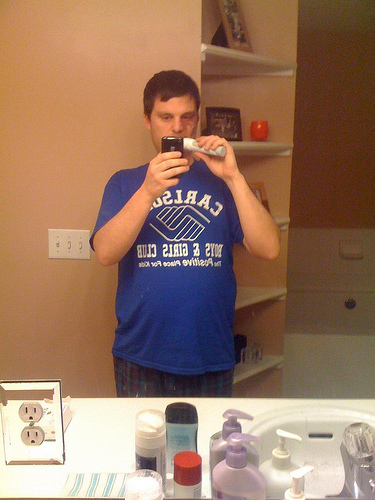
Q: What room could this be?
A: It is a bathroom.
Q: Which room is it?
A: It is a bathroom.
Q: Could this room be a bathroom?
A: Yes, it is a bathroom.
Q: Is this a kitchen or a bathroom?
A: It is a bathroom.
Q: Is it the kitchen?
A: No, it is the bathroom.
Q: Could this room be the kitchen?
A: No, it is the bathroom.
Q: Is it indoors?
A: Yes, it is indoors.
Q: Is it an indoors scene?
A: Yes, it is indoors.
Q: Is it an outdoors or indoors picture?
A: It is indoors.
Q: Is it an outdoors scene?
A: No, it is indoors.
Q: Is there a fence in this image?
A: No, there are no fences.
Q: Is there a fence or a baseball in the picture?
A: No, there are no fences or baseballs.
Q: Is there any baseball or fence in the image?
A: No, there are no fences or baseballs.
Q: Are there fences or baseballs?
A: No, there are no fences or baseballs.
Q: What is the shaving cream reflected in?
A: The shaving cream is reflected in the mirror.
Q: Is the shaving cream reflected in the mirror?
A: Yes, the shaving cream is reflected in the mirror.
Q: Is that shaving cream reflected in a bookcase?
A: No, the shaving cream is reflected in the mirror.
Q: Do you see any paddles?
A: No, there are no paddles.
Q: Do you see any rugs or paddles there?
A: No, there are no paddles or rugs.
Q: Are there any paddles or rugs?
A: No, there are no paddles or rugs.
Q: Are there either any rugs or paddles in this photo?
A: No, there are no paddles or rugs.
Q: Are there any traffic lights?
A: No, there are no traffic lights.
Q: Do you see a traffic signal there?
A: No, there are no traffic lights.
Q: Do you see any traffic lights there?
A: No, there are no traffic lights.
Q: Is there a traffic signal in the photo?
A: No, there are no traffic lights.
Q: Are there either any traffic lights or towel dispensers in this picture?
A: No, there are no traffic lights or towel dispensers.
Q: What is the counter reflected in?
A: The counter is reflected in the mirror.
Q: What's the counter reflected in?
A: The counter is reflected in the mirror.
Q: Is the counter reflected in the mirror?
A: Yes, the counter is reflected in the mirror.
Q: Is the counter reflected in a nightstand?
A: No, the counter is reflected in the mirror.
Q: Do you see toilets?
A: No, there are no toilets.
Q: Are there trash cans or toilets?
A: No, there are no toilets or trash cans.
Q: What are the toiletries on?
A: The toiletries are on the counter.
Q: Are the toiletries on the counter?
A: Yes, the toiletries are on the counter.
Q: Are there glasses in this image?
A: No, there are no glasses.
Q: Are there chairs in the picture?
A: No, there are no chairs.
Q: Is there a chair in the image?
A: No, there are no chairs.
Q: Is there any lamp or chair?
A: No, there are no chairs or lamps.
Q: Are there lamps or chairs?
A: No, there are no chairs or lamps.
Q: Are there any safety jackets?
A: No, there are no safety jackets.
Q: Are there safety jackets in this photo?
A: No, there are no safety jackets.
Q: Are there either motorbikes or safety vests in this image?
A: No, there are no safety vests or motorbikes.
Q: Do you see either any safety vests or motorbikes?
A: No, there are no safety vests or motorbikes.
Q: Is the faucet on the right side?
A: Yes, the faucet is on the right of the image.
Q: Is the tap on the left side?
A: No, the tap is on the right of the image.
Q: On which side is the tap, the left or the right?
A: The tap is on the right of the image.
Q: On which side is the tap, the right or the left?
A: The tap is on the right of the image.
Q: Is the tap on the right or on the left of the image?
A: The tap is on the right of the image.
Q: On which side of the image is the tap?
A: The tap is on the right of the image.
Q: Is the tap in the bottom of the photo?
A: Yes, the tap is in the bottom of the image.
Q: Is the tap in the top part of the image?
A: No, the tap is in the bottom of the image.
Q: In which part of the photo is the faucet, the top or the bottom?
A: The faucet is in the bottom of the image.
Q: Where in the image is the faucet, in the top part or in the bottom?
A: The faucet is in the bottom of the image.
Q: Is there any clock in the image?
A: No, there are no clocks.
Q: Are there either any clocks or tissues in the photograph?
A: No, there are no clocks or tissues.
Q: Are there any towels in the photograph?
A: Yes, there is a towel.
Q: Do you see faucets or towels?
A: Yes, there is a towel.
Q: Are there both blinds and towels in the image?
A: No, there is a towel but no blinds.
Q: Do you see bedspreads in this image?
A: No, there are no bedspreads.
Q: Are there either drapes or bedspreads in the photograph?
A: No, there are no bedspreads or drapes.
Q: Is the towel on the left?
A: Yes, the towel is on the left of the image.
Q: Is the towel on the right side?
A: No, the towel is on the left of the image.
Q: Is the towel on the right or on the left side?
A: The towel is on the left of the image.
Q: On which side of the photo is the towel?
A: The towel is on the left of the image.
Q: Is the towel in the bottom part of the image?
A: Yes, the towel is in the bottom of the image.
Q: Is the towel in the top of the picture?
A: No, the towel is in the bottom of the image.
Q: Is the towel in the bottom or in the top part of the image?
A: The towel is in the bottom of the image.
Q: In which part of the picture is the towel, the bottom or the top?
A: The towel is in the bottom of the image.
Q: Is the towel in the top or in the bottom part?
A: The towel is in the bottom of the image.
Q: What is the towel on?
A: The towel is on the counter.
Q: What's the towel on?
A: The towel is on the counter.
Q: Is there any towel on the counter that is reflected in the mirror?
A: Yes, there is a towel on the counter.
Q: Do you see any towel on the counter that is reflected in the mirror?
A: Yes, there is a towel on the counter.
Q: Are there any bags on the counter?
A: No, there is a towel on the counter.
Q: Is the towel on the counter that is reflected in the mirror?
A: Yes, the towel is on the counter.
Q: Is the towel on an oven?
A: No, the towel is on the counter.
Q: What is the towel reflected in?
A: The towel is reflected in the mirror.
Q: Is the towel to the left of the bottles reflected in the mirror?
A: Yes, the towel is reflected in the mirror.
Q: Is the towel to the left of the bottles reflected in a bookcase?
A: No, the towel is reflected in the mirror.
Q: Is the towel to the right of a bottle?
A: No, the towel is to the left of a bottle.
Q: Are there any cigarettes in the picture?
A: No, there are no cigarettes.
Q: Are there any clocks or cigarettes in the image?
A: No, there are no cigarettes or clocks.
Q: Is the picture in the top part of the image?
A: Yes, the picture is in the top of the image.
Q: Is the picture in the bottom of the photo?
A: No, the picture is in the top of the image.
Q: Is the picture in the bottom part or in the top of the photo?
A: The picture is in the top of the image.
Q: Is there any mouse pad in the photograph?
A: No, there are no mouse pads.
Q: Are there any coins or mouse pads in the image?
A: No, there are no mouse pads or coins.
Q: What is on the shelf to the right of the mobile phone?
A: The picture frame is on the shelf.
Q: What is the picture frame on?
A: The picture frame is on the shelf.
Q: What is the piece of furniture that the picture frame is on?
A: The piece of furniture is a shelf.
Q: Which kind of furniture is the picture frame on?
A: The picture frame is on the shelf.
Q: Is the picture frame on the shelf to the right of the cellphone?
A: Yes, the picture frame is on the shelf.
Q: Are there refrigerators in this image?
A: No, there are no refrigerators.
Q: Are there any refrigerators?
A: No, there are no refrigerators.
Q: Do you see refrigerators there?
A: No, there are no refrigerators.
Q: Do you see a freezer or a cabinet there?
A: No, there are no refrigerators or cabinets.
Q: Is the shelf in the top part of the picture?
A: Yes, the shelf is in the top of the image.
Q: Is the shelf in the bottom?
A: No, the shelf is in the top of the image.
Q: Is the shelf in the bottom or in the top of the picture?
A: The shelf is in the top of the image.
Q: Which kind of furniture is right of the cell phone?
A: The piece of furniture is a shelf.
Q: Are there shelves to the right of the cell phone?
A: Yes, there is a shelf to the right of the cell phone.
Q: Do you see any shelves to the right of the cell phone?
A: Yes, there is a shelf to the right of the cell phone.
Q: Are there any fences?
A: No, there are no fences.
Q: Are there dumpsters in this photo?
A: No, there are no dumpsters.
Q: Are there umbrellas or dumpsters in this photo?
A: No, there are no dumpsters or umbrellas.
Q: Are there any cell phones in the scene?
A: Yes, there is a cell phone.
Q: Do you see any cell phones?
A: Yes, there is a cell phone.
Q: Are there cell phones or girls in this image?
A: Yes, there is a cell phone.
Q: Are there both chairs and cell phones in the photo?
A: No, there is a cell phone but no chairs.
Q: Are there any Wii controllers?
A: No, there are no Wii controllers.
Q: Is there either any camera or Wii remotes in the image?
A: No, there are no Wii controllers or cameras.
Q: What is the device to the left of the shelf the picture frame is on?
A: The device is a cell phone.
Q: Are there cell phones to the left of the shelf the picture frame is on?
A: Yes, there is a cell phone to the left of the shelf.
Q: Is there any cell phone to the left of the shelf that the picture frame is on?
A: Yes, there is a cell phone to the left of the shelf.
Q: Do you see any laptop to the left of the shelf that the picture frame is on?
A: No, there is a cell phone to the left of the shelf.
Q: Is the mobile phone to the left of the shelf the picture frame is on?
A: Yes, the mobile phone is to the left of the shelf.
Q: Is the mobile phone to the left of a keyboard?
A: No, the mobile phone is to the left of the shelf.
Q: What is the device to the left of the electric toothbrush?
A: The device is a cell phone.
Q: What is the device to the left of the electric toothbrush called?
A: The device is a cell phone.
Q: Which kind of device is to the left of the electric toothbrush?
A: The device is a cell phone.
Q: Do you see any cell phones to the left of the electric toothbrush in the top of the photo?
A: Yes, there is a cell phone to the left of the electric toothbrush.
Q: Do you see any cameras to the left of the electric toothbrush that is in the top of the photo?
A: No, there is a cell phone to the left of the electric toothbrush.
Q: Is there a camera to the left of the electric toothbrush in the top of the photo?
A: No, there is a cell phone to the left of the electric toothbrush.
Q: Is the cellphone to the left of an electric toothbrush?
A: Yes, the cellphone is to the left of an electric toothbrush.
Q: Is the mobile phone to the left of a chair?
A: No, the mobile phone is to the left of an electric toothbrush.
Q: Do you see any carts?
A: No, there are no carts.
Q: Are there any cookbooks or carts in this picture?
A: No, there are no carts or cookbooks.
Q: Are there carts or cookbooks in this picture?
A: No, there are no carts or cookbooks.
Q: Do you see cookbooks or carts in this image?
A: No, there are no carts or cookbooks.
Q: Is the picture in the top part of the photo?
A: Yes, the picture is in the top of the image.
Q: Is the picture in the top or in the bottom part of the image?
A: The picture is in the top of the image.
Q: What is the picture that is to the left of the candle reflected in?
A: The picture is reflected in the mirror.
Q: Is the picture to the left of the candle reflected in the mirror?
A: Yes, the picture is reflected in the mirror.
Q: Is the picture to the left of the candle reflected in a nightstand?
A: No, the picture is reflected in the mirror.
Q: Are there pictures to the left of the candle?
A: Yes, there is a picture to the left of the candle.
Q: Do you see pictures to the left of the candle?
A: Yes, there is a picture to the left of the candle.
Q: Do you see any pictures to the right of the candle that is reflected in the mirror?
A: No, the picture is to the left of the candle.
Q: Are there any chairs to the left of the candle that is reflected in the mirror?
A: No, there is a picture to the left of the candle.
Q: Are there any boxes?
A: No, there are no boxes.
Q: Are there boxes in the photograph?
A: No, there are no boxes.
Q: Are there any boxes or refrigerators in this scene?
A: No, there are no boxes or refrigerators.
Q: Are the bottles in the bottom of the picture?
A: Yes, the bottles are in the bottom of the image.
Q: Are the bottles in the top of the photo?
A: No, the bottles are in the bottom of the image.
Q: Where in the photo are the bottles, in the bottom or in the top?
A: The bottles are in the bottom of the image.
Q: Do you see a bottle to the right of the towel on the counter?
A: Yes, there are bottles to the right of the towel.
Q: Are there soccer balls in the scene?
A: No, there are no soccer balls.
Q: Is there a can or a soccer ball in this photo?
A: No, there are no soccer balls or cans.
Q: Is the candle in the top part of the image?
A: Yes, the candle is in the top of the image.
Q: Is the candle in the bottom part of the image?
A: No, the candle is in the top of the image.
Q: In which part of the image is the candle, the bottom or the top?
A: The candle is in the top of the image.